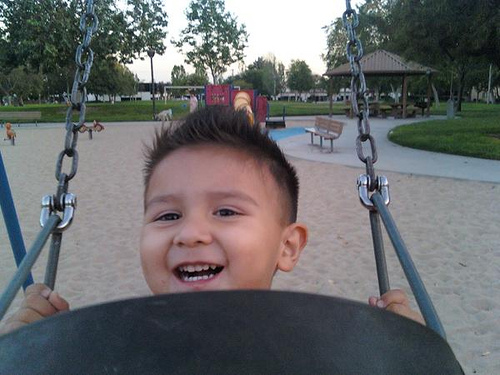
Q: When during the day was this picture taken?
A: Daytime.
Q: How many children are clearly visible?
A: One.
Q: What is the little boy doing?
A: Swinging.